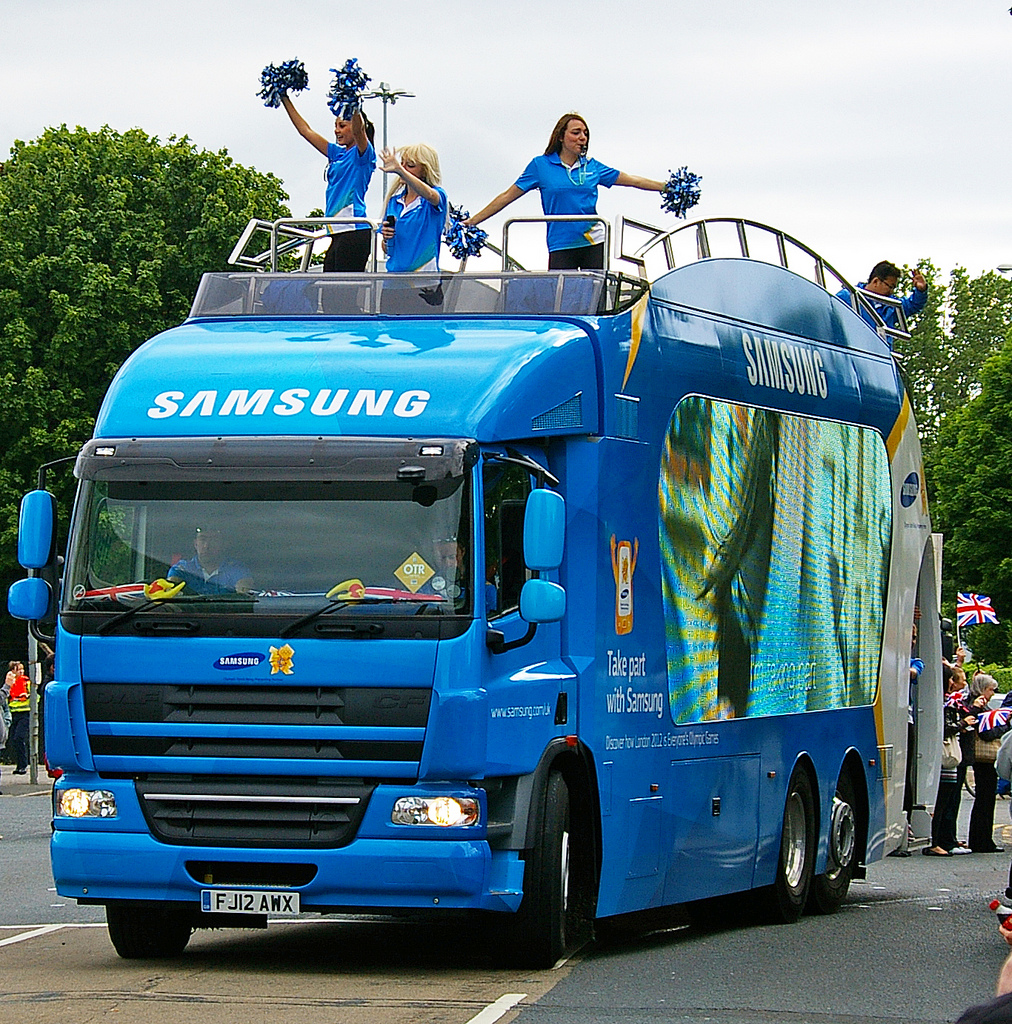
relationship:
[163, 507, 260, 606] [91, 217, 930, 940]
passenger inside truck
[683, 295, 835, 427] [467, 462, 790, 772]
letter on bus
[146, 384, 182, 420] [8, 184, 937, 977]
letter on bus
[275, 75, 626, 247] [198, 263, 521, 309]
people on roof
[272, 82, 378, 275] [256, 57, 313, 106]
woman holding pom-poms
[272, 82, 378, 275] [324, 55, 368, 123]
woman holding pom-poms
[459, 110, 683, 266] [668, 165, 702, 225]
woman holding pom-poms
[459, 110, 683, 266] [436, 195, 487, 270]
woman holding pom-poms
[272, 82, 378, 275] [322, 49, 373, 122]
woman holding pom-poms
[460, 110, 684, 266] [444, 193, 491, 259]
woman holding pom-poms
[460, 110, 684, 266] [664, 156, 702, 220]
woman holding pom-poms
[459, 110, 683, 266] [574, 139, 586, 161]
woman has a wistle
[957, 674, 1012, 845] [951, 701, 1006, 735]
person carrying flag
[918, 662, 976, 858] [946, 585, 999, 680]
person carrying flag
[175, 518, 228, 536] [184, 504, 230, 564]
sunglasses on head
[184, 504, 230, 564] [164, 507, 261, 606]
head on passenger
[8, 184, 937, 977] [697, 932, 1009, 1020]
bus on street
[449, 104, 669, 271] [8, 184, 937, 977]
person on top of bus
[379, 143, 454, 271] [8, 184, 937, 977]
person on top of bus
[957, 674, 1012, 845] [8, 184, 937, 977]
person on top of bus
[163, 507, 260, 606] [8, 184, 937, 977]
passenger riding inside bus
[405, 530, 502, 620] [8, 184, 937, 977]
man riding inside bus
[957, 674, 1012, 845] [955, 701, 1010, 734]
person holding flag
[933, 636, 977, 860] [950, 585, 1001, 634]
person holding flag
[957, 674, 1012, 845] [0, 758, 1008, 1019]
person standing on street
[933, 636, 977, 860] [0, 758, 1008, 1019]
person standing on street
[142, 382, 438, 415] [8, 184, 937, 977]
lettering on bus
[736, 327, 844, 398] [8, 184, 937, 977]
lettering on bus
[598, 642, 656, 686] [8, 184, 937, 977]
lettering on bus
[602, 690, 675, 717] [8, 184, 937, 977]
lettering on bus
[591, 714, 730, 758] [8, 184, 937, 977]
lettering on bus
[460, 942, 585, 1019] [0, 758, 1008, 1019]
line on street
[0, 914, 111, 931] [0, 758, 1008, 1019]
line on street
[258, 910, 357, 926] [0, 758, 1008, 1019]
line on street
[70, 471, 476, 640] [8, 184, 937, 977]
windshield on bus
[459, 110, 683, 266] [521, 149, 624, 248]
woman wearing shirt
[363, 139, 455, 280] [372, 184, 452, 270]
woman wearing shirt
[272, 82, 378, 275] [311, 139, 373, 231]
woman wearing shirt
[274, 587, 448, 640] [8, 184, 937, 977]
windshield wipers on bus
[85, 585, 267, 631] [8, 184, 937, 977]
windshield wipers on bus